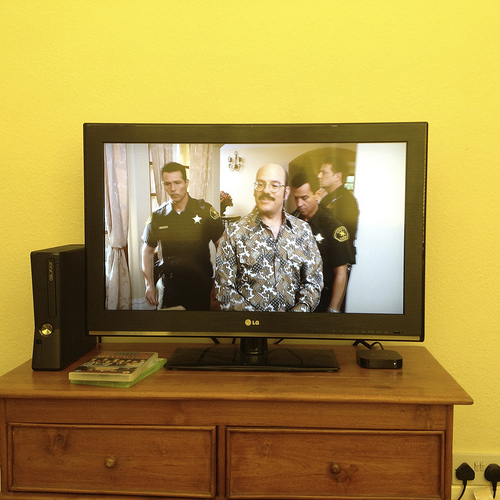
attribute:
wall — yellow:
[2, 3, 494, 499]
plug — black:
[456, 461, 479, 500]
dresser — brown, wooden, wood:
[2, 339, 478, 500]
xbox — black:
[27, 244, 101, 373]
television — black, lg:
[80, 119, 430, 377]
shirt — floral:
[212, 210, 328, 312]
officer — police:
[140, 159, 230, 310]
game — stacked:
[66, 346, 169, 391]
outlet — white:
[455, 452, 499, 491]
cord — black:
[487, 482, 499, 499]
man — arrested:
[212, 158, 328, 319]